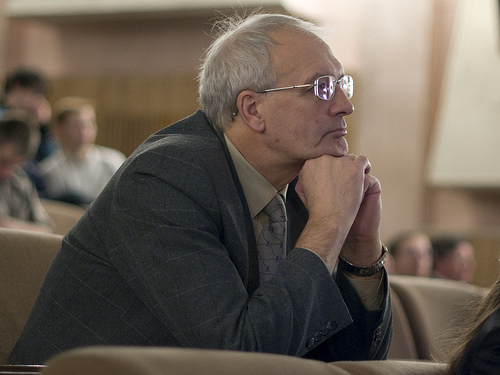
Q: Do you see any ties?
A: Yes, there is a tie.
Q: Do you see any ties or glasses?
A: Yes, there is a tie.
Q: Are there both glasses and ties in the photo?
A: Yes, there are both a tie and glasses.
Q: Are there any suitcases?
A: No, there are no suitcases.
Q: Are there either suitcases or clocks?
A: No, there are no suitcases or clocks.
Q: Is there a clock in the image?
A: No, there are no clocks.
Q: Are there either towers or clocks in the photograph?
A: No, there are no clocks or towers.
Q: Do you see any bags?
A: No, there are no bags.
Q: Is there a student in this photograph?
A: No, there are no students.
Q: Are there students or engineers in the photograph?
A: No, there are no students or engineers.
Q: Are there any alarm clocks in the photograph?
A: No, there are no alarm clocks.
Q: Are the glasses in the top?
A: Yes, the glasses are in the top of the image.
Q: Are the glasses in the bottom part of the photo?
A: No, the glasses are in the top of the image.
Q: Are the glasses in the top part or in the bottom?
A: The glasses are in the top of the image.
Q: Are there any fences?
A: No, there are no fences.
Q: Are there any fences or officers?
A: No, there are no fences or officers.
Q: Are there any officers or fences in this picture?
A: No, there are no fences or officers.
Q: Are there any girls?
A: No, there are no girls.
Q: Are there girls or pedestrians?
A: No, there are no girls or pedestrians.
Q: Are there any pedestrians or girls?
A: No, there are no girls or pedestrians.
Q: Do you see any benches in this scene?
A: No, there are no benches.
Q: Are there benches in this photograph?
A: No, there are no benches.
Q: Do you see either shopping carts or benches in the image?
A: No, there are no benches or shopping carts.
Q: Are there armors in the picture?
A: No, there are no armors.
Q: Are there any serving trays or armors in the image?
A: No, there are no armors or serving trays.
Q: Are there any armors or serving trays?
A: No, there are no armors or serving trays.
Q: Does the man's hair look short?
A: Yes, the hair is short.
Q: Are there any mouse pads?
A: No, there are no mouse pads.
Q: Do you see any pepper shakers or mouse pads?
A: No, there are no mouse pads or pepper shakers.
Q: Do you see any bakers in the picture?
A: No, there are no bakers.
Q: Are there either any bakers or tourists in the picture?
A: No, there are no bakers or tourists.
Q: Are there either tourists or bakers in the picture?
A: No, there are no bakers or tourists.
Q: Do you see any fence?
A: No, there are no fences.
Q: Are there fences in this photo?
A: No, there are no fences.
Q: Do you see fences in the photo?
A: No, there are no fences.